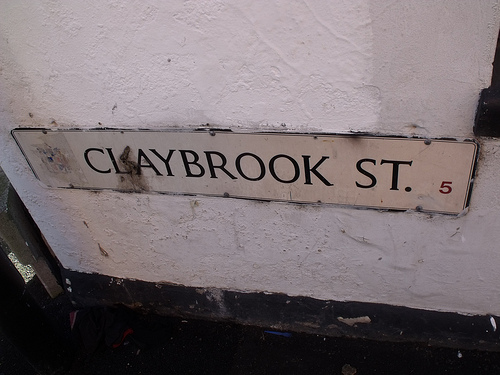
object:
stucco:
[1, 0, 389, 306]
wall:
[0, 0, 499, 353]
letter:
[83, 147, 112, 174]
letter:
[104, 144, 133, 177]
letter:
[132, 148, 163, 177]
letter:
[148, 147, 176, 177]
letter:
[177, 148, 206, 179]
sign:
[11, 120, 478, 218]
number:
[438, 179, 453, 194]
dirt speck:
[92, 238, 110, 262]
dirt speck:
[81, 219, 91, 233]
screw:
[208, 130, 217, 137]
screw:
[222, 192, 231, 199]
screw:
[423, 137, 432, 146]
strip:
[61, 258, 499, 348]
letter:
[202, 148, 238, 180]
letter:
[235, 152, 265, 182]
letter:
[302, 151, 336, 189]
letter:
[379, 156, 413, 192]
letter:
[352, 157, 379, 189]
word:
[84, 143, 339, 188]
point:
[404, 184, 414, 194]